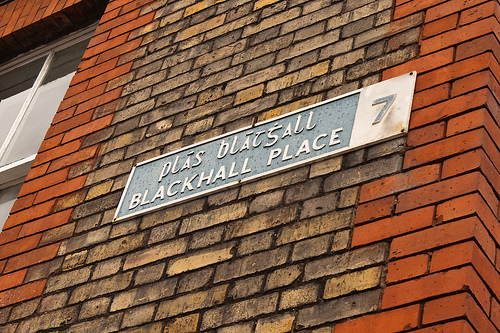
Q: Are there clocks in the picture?
A: No, there are no clocks.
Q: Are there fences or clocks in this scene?
A: No, there are no clocks or fences.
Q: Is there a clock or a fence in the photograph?
A: No, there are no clocks or fences.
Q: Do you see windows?
A: Yes, there is a window.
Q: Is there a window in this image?
A: Yes, there is a window.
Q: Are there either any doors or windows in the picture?
A: Yes, there is a window.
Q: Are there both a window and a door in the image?
A: No, there is a window but no doors.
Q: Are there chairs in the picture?
A: No, there are no chairs.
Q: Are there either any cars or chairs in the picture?
A: No, there are no chairs or cars.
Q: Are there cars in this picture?
A: No, there are no cars.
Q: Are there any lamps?
A: No, there are no lamps.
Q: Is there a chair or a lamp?
A: No, there are no lamps or chairs.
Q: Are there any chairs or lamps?
A: No, there are no lamps or chairs.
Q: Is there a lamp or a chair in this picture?
A: No, there are no lamps or chairs.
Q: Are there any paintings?
A: No, there are no paintings.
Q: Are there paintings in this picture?
A: No, there are no paintings.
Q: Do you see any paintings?
A: No, there are no paintings.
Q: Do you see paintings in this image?
A: No, there are no paintings.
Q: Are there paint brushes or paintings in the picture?
A: No, there are no paintings or paint brushes.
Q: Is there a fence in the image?
A: No, there are no fences.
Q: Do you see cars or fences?
A: No, there are no fences or cars.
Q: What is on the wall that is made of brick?
A: The sign is on the wall.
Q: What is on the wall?
A: The sign is on the wall.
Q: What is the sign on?
A: The sign is on the wall.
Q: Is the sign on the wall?
A: Yes, the sign is on the wall.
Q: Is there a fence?
A: No, there are no fences.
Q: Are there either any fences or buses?
A: No, there are no fences or buses.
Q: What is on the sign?
A: The number is on the sign.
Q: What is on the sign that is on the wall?
A: The number is on the sign.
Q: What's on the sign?
A: The number is on the sign.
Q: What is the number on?
A: The number is on the sign.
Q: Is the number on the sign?
A: Yes, the number is on the sign.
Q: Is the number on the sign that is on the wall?
A: Yes, the number is on the sign.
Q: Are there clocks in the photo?
A: No, there are no clocks.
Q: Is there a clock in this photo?
A: No, there are no clocks.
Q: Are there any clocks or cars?
A: No, there are no clocks or cars.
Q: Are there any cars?
A: No, there are no cars.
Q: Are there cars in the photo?
A: No, there are no cars.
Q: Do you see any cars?
A: No, there are no cars.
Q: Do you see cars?
A: No, there are no cars.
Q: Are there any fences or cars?
A: No, there are no cars or fences.